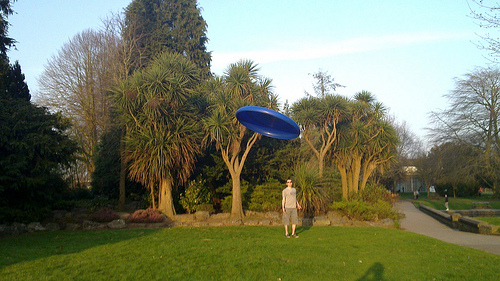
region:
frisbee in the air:
[241, 103, 305, 150]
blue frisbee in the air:
[225, 90, 310, 150]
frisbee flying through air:
[235, 94, 303, 154]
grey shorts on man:
[272, 208, 299, 230]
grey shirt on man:
[272, 187, 295, 207]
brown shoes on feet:
[275, 229, 298, 241]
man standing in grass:
[263, 174, 310, 258]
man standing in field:
[270, 176, 310, 241]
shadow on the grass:
[355, 259, 400, 279]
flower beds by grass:
[40, 206, 155, 243]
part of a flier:
[260, 115, 269, 120]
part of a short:
[285, 211, 301, 229]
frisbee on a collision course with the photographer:
[228, 98, 310, 149]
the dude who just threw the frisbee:
[275, 171, 308, 243]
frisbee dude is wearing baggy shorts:
[276, 171, 306, 242]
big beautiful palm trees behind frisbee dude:
[101, 47, 279, 229]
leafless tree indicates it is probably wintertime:
[27, 22, 138, 202]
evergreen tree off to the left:
[2, 0, 94, 232]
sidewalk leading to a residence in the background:
[377, 148, 497, 256]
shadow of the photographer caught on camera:
[351, 251, 393, 279]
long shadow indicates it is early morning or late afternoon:
[270, 171, 325, 246]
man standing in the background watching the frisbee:
[276, 173, 306, 239]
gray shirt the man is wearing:
[281, 184, 298, 209]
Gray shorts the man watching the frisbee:
[279, 206, 301, 228]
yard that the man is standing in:
[4, 223, 498, 280]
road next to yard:
[387, 196, 498, 262]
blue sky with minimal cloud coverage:
[4, 0, 497, 160]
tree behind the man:
[290, 93, 352, 178]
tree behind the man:
[111, 52, 213, 219]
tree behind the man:
[204, 54, 275, 221]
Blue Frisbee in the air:
[236, 100, 302, 144]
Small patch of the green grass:
[242, 248, 275, 270]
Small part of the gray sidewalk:
[422, 215, 438, 233]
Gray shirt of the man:
[283, 190, 295, 201]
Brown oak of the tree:
[228, 188, 246, 216]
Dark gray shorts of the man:
[284, 209, 295, 226]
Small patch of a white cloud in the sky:
[322, 43, 342, 54]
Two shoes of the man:
[286, 232, 300, 241]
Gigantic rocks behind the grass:
[184, 210, 209, 224]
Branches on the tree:
[51, 58, 84, 99]